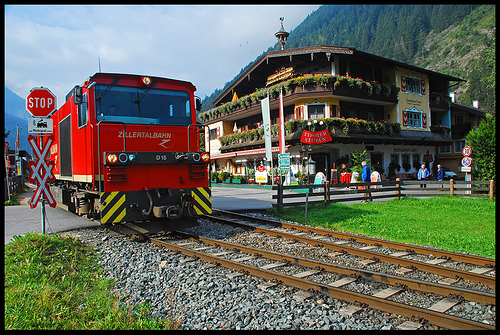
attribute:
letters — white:
[26, 96, 56, 107]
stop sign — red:
[23, 88, 56, 118]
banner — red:
[295, 128, 336, 145]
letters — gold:
[300, 132, 328, 145]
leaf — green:
[372, 13, 397, 34]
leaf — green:
[409, 23, 415, 32]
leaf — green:
[321, 12, 330, 25]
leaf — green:
[391, 22, 401, 34]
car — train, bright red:
[42, 70, 214, 230]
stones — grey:
[134, 221, 379, 291]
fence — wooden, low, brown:
[268, 174, 484, 209]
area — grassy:
[346, 198, 485, 241]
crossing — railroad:
[14, 180, 257, 228]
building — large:
[206, 39, 485, 187]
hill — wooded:
[207, 4, 484, 114]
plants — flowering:
[209, 74, 378, 108]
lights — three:
[304, 120, 326, 127]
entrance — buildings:
[302, 146, 332, 182]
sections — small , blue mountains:
[0, 81, 24, 146]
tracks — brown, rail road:
[177, 215, 452, 332]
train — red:
[36, 69, 212, 230]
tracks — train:
[186, 215, 484, 317]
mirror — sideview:
[34, 84, 80, 136]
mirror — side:
[70, 70, 84, 128]